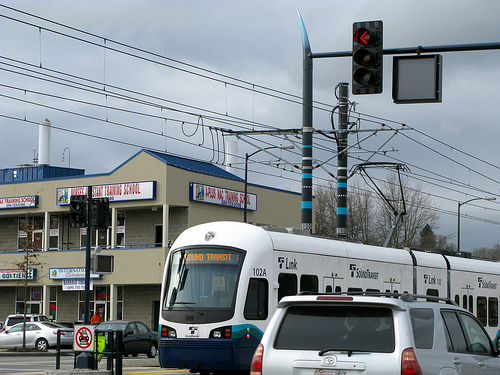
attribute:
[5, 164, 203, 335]
building — commercial, two-story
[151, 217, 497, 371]
train — long, white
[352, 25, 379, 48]
arrow — red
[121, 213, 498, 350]
train — commuter , light rail 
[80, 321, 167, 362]
car — black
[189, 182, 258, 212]
sign — white, plastic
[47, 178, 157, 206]
sign — white, red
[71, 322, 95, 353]
sign — for traffic, red, white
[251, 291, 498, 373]
stationwagon — silver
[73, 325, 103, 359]
sign — white, square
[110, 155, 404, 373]
train — light rail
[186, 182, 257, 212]
store sign — red, white, rectanglular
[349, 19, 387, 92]
traffic light — black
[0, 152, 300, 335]
building — tan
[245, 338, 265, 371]
tail light — red